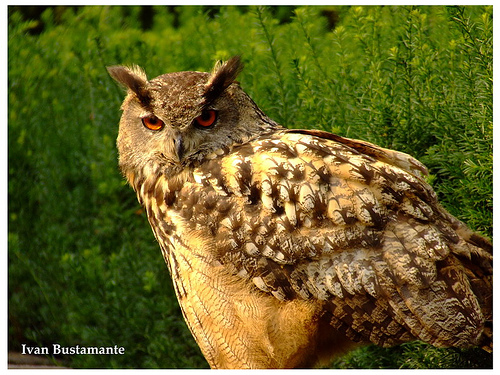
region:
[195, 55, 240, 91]
ear on an owl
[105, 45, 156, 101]
ear on an owl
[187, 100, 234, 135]
eye on an owl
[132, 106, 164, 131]
eye of an owl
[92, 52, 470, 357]
owl in the trees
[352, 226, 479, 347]
feather on an owl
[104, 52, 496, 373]
the owl is large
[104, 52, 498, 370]
the owl is fluffy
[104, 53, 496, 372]
the owl has a lot of feathers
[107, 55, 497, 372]
the owl is brown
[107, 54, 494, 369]
the owl has two eyes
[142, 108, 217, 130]
the eyes are light brown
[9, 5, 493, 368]
the greenery behind the owl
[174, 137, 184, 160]
the small black nose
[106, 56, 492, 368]
the dark brown feathers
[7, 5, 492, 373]
the name near the owl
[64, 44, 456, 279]
this is a bird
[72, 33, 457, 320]
this is an owl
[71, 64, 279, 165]
the owl has red eyes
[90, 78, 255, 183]
the owl looks mad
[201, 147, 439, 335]
the feathers are white and black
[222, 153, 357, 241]
the wing is patterned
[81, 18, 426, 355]
this is a wild animal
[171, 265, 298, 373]
the stomach is yellow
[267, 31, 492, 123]
the trees have pine needles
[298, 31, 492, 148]
the pine needles are green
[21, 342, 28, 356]
white print style letter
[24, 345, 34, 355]
white print style letter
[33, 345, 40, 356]
white print style letter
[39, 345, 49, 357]
white print style letter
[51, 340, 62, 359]
white print style letter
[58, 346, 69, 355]
white print style letter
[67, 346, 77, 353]
white print style letter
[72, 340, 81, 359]
white print style letter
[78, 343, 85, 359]
white print style letter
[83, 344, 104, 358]
white print style letter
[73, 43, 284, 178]
head of the owl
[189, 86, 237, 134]
eye of the owl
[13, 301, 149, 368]
words in bottom left corner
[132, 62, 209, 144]
top of the bird's head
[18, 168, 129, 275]
green grass near the owl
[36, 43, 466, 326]
one owl looking near the camera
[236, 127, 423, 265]
light and dark feathers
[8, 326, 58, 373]
first name of a person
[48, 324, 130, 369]
last name of person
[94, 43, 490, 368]
brown and tan owl in grass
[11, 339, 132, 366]
person's name in white print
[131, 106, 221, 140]
two red owl eyes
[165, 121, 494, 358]
black and tan feathers on owl back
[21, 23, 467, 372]
an owl looking in the woods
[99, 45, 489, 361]
Owl sitting on a branch